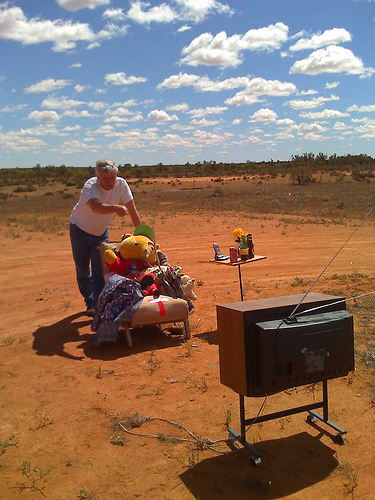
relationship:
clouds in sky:
[0, 1, 375, 159] [0, 0, 373, 160]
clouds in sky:
[165, 69, 297, 111] [0, 0, 373, 160]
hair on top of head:
[94, 157, 120, 173] [83, 155, 122, 188]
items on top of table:
[209, 224, 254, 261] [207, 251, 266, 302]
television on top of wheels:
[219, 281, 344, 403] [224, 413, 346, 465]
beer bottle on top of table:
[245, 230, 255, 259] [232, 255, 247, 266]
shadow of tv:
[178, 429, 340, 498] [215, 289, 355, 400]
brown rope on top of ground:
[111, 398, 242, 453] [294, 234, 334, 254]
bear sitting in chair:
[104, 234, 161, 281] [108, 242, 189, 344]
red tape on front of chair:
[155, 297, 174, 327] [139, 295, 181, 328]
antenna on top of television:
[285, 204, 362, 319] [197, 275, 365, 397]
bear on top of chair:
[104, 231, 159, 278] [98, 237, 192, 346]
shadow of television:
[178, 429, 340, 498] [216, 292, 355, 398]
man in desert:
[62, 150, 136, 302] [0, 180, 373, 499]